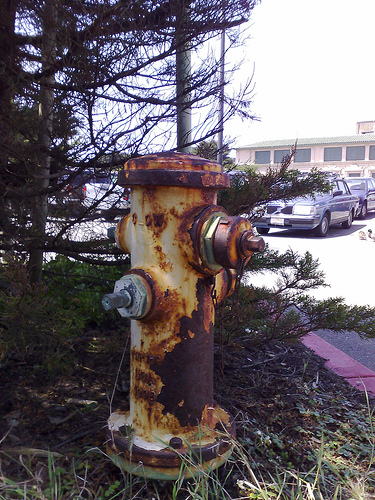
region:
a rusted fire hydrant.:
[71, 127, 273, 481]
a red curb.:
[246, 296, 372, 398]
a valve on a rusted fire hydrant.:
[88, 235, 154, 350]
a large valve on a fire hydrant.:
[183, 196, 283, 285]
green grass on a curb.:
[1, 265, 374, 494]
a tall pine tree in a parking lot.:
[1, 0, 339, 318]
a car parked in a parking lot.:
[245, 167, 361, 241]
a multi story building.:
[233, 117, 374, 185]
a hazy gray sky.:
[1, 2, 372, 157]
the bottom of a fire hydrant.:
[86, 384, 250, 480]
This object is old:
[87, 126, 278, 481]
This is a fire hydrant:
[80, 139, 281, 473]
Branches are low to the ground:
[5, 218, 374, 374]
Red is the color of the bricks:
[267, 283, 374, 403]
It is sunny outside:
[208, 11, 332, 117]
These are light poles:
[158, 5, 256, 318]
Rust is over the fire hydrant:
[102, 131, 280, 493]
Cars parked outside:
[245, 139, 368, 255]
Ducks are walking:
[341, 216, 374, 243]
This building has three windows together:
[242, 146, 315, 167]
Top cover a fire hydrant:
[113, 147, 234, 189]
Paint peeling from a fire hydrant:
[143, 360, 179, 412]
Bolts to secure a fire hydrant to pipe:
[166, 433, 189, 453]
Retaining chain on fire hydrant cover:
[211, 264, 250, 332]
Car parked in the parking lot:
[249, 174, 358, 240]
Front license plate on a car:
[269, 215, 285, 226]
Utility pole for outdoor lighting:
[215, 2, 223, 160]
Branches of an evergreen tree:
[290, 292, 373, 341]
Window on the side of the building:
[320, 145, 344, 162]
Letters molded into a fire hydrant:
[130, 347, 167, 406]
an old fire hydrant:
[45, 100, 291, 436]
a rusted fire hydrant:
[84, 182, 319, 486]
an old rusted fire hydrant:
[88, 199, 289, 464]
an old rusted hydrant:
[39, 165, 354, 499]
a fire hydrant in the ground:
[80, 152, 281, 497]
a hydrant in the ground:
[91, 166, 282, 486]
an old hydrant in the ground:
[116, 174, 275, 479]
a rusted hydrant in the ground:
[56, 158, 246, 486]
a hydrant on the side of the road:
[75, 178, 374, 476]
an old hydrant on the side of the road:
[77, 163, 365, 475]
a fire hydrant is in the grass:
[99, 150, 265, 480]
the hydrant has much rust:
[98, 152, 265, 481]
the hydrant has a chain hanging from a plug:
[193, 203, 269, 381]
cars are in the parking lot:
[5, 167, 374, 261]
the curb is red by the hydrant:
[238, 268, 374, 411]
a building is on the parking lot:
[224, 118, 374, 232]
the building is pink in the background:
[231, 121, 374, 222]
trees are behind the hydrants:
[6, 4, 372, 482]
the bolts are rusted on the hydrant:
[109, 395, 233, 469]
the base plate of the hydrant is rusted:
[103, 394, 237, 478]